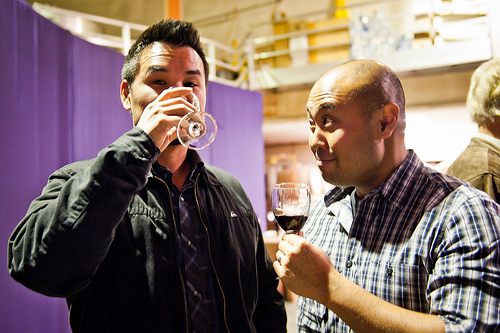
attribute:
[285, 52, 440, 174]
head — bald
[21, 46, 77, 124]
wall — purple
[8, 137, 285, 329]
jacket — green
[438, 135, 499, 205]
jacket — brown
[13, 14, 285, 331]
man — dark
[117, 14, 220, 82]
hair — short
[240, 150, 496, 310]
shirt — button up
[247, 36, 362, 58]
rails — gray, metal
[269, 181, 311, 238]
wine glass — clear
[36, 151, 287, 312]
shirt — long, sleeved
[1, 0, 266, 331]
purple sheet — long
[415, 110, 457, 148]
wall — white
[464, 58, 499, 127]
hair — gray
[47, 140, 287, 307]
jacket — black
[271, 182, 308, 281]
glass — wine glass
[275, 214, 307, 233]
wine — red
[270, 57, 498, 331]
man — bald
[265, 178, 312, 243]
glass — half full